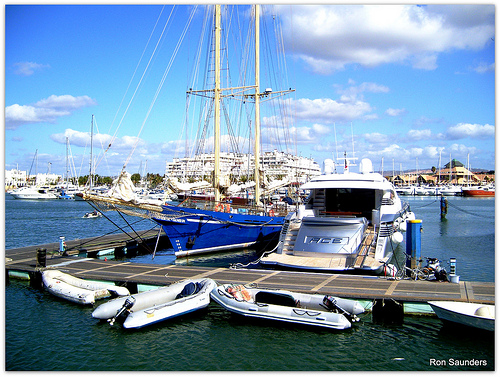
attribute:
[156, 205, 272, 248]
boat — one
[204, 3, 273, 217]
masts — tall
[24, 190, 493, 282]
water — blue, green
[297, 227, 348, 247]
word — one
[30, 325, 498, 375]
water — green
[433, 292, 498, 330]
boat — small, white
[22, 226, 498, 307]
dock — grey, L-shaped, long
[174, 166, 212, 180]
wall — one